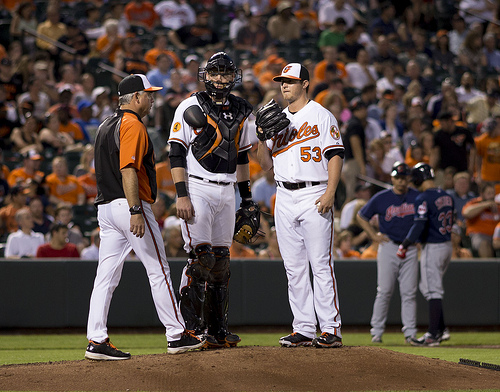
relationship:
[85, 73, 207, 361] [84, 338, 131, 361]
man has shoe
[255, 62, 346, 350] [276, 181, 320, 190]
man has belt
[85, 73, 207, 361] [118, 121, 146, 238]
man has arm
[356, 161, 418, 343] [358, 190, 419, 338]
man wearing uniform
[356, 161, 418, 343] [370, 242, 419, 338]
man wearing pants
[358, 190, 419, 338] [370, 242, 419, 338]
uniform has pants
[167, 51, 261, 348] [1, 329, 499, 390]
gear on top of field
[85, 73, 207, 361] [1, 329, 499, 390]
man on top of field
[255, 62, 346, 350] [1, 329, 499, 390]
man on top of field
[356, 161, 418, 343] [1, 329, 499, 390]
man on top of field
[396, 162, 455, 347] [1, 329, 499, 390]
player on top of field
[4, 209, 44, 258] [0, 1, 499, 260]
fan inside of stands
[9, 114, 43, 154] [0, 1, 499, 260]
fan inside of stands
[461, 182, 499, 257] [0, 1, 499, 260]
fan inside of stands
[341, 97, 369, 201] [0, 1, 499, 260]
fan inside of stands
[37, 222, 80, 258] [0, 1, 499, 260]
fan inside of stands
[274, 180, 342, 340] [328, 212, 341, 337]
pants have stripe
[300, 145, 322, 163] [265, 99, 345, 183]
53 written on shirt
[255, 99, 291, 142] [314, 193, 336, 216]
glove covering hand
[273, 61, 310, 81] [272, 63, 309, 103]
cap on top of head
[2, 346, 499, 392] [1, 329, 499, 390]
mound on top of field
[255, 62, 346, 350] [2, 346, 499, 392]
man standing on mound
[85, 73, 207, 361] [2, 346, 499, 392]
man standing on mound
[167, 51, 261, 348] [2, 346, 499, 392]
gear standing on mound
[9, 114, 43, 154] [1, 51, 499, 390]
fan watching game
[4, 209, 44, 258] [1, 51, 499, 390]
fan watching game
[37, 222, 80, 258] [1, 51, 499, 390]
fan watching game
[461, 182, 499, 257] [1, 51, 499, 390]
fan watching game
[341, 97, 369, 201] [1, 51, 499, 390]
fan watching game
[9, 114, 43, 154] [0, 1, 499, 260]
fan inside stands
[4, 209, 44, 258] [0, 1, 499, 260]
fan inside stands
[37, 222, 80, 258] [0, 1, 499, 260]
fan inside stands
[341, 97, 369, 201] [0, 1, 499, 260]
fan inside stands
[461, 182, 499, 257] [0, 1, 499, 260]
fan inside stands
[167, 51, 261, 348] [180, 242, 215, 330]
gear wearing protection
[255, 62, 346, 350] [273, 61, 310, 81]
man wearing cap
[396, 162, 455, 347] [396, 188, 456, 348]
player wearing uniform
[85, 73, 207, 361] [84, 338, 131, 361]
man wearing shoe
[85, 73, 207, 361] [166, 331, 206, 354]
man wearing shoe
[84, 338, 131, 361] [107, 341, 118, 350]
shoe has shoelaces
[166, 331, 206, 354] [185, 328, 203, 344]
shoe has shoelaces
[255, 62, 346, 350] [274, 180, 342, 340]
man wearing pants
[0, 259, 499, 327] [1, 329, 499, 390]
fence separating field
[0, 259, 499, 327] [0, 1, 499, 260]
fence separating stands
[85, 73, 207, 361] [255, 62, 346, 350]
man talking to man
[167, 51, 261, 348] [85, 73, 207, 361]
gear talking to man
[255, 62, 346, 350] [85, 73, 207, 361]
man talking to man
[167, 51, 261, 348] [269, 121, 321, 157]
gear for orioles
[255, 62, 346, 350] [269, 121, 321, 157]
man for orioles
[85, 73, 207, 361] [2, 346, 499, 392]
man walking on mound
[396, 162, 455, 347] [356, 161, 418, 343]
player talking to man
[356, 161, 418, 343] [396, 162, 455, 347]
man talking to player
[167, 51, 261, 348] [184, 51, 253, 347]
gear wearing gear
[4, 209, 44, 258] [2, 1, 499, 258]
fan inside of crowd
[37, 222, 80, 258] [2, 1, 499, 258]
fan inside of crowd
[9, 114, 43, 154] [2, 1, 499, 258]
fan inside of crowd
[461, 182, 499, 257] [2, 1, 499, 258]
fan inside of crowd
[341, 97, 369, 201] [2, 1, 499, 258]
fan inside of crowd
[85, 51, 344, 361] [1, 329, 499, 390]
team on top of field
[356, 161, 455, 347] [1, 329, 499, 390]
team on top of field